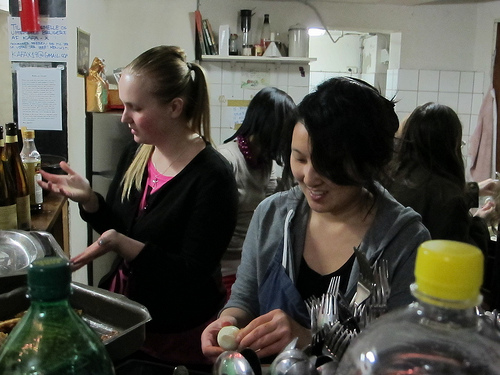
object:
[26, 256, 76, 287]
bottle cap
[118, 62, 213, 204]
pony tail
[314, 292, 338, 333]
forks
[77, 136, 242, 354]
sweater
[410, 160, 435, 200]
ground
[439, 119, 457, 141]
ground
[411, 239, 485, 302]
cap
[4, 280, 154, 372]
cooking tray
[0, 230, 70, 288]
cooking tray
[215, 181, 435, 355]
jacket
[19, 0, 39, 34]
hydrant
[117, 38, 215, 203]
blonde hair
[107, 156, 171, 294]
shirt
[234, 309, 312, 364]
hands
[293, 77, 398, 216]
hair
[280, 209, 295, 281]
string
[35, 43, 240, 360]
blonde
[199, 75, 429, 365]
girl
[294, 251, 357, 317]
shirt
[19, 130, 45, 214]
bottles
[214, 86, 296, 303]
lady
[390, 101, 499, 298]
lady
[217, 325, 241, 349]
egg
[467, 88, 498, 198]
jacket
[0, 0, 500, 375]
kitchen